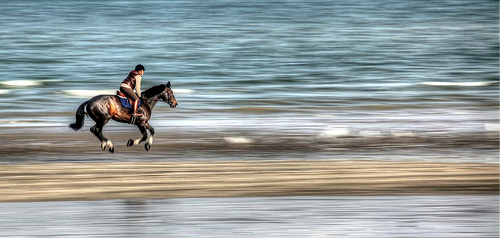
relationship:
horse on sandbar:
[66, 81, 176, 154] [0, 164, 499, 203]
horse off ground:
[66, 81, 176, 154] [0, 162, 499, 236]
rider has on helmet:
[120, 63, 145, 118] [136, 63, 146, 72]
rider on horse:
[120, 63, 145, 118] [66, 81, 176, 154]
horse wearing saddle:
[66, 81, 176, 154] [118, 89, 141, 127]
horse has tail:
[66, 81, 176, 154] [68, 100, 88, 130]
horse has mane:
[66, 81, 176, 154] [143, 83, 164, 99]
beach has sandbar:
[0, 162, 499, 236] [0, 164, 499, 203]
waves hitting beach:
[0, 78, 500, 134] [0, 164, 499, 203]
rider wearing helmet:
[120, 63, 145, 118] [136, 63, 146, 72]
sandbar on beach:
[0, 164, 499, 203] [0, 162, 499, 236]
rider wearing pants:
[120, 63, 145, 118] [120, 87, 141, 100]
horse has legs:
[66, 81, 176, 154] [142, 118, 156, 148]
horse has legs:
[66, 81, 176, 154] [127, 124, 148, 148]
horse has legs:
[66, 81, 176, 154] [99, 120, 116, 155]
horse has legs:
[66, 81, 176, 154] [90, 121, 107, 149]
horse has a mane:
[66, 81, 176, 154] [143, 83, 164, 99]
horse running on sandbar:
[66, 81, 176, 154] [0, 164, 499, 203]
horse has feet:
[66, 81, 176, 154] [144, 143, 151, 153]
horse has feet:
[66, 81, 176, 154] [127, 138, 134, 148]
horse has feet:
[66, 81, 176, 154] [108, 146, 114, 153]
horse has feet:
[66, 81, 176, 154] [102, 143, 108, 150]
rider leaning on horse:
[120, 63, 145, 118] [66, 81, 176, 154]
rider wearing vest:
[120, 63, 145, 118] [123, 71, 136, 87]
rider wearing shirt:
[120, 63, 145, 118] [118, 73, 143, 94]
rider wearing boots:
[120, 63, 145, 118] [131, 99, 140, 116]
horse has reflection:
[66, 81, 176, 154] [106, 191, 152, 220]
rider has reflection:
[120, 63, 145, 118] [114, 210, 163, 229]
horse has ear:
[66, 81, 176, 154] [166, 80, 172, 86]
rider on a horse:
[120, 63, 145, 118] [66, 81, 176, 154]